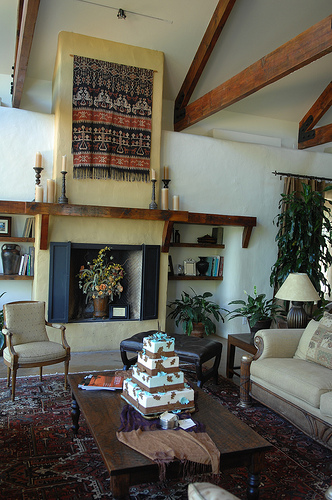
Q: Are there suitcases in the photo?
A: No, there are no suitcases.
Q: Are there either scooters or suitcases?
A: No, there are no suitcases or scooters.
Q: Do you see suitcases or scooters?
A: No, there are no suitcases or scooters.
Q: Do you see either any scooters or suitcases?
A: No, there are no suitcases or scooters.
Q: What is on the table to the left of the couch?
A: The plant is on the table.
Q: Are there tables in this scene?
A: Yes, there is a table.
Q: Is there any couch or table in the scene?
A: Yes, there is a table.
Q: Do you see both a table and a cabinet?
A: No, there is a table but no cabinets.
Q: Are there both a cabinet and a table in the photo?
A: No, there is a table but no cabinets.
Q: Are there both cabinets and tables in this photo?
A: No, there is a table but no cabinets.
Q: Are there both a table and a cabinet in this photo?
A: No, there is a table but no cabinets.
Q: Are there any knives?
A: No, there are no knives.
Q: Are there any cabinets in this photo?
A: No, there are no cabinets.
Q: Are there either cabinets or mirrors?
A: No, there are no cabinets or mirrors.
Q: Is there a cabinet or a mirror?
A: No, there are no cabinets or mirrors.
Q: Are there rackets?
A: No, there are no rackets.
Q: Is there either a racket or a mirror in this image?
A: No, there are no rackets or mirrors.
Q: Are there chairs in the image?
A: Yes, there is a chair.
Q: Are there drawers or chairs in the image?
A: Yes, there is a chair.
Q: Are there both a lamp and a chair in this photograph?
A: Yes, there are both a chair and a lamp.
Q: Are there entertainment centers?
A: No, there are no entertainment centers.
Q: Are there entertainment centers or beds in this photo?
A: No, there are no entertainment centers or beds.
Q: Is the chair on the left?
A: Yes, the chair is on the left of the image.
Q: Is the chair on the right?
A: No, the chair is on the left of the image.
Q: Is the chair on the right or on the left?
A: The chair is on the left of the image.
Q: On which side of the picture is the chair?
A: The chair is on the left of the image.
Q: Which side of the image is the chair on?
A: The chair is on the left of the image.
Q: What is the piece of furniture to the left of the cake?
A: The piece of furniture is a chair.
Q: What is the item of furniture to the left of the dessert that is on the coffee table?
A: The piece of furniture is a chair.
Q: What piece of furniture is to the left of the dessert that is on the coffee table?
A: The piece of furniture is a chair.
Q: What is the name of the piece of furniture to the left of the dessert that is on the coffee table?
A: The piece of furniture is a chair.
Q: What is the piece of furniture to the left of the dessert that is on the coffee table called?
A: The piece of furniture is a chair.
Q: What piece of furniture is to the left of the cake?
A: The piece of furniture is a chair.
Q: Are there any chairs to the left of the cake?
A: Yes, there is a chair to the left of the cake.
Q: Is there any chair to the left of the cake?
A: Yes, there is a chair to the left of the cake.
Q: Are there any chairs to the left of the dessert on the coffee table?
A: Yes, there is a chair to the left of the cake.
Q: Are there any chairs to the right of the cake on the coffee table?
A: No, the chair is to the left of the cake.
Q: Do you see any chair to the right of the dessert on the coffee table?
A: No, the chair is to the left of the cake.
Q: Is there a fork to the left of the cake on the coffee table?
A: No, there is a chair to the left of the cake.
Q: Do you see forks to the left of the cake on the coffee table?
A: No, there is a chair to the left of the cake.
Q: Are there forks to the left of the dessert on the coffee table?
A: No, there is a chair to the left of the cake.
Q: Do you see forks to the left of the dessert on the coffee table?
A: No, there is a chair to the left of the cake.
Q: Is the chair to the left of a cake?
A: Yes, the chair is to the left of a cake.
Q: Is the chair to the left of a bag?
A: No, the chair is to the left of a cake.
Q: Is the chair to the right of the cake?
A: No, the chair is to the left of the cake.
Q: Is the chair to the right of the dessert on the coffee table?
A: No, the chair is to the left of the cake.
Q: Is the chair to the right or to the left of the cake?
A: The chair is to the left of the cake.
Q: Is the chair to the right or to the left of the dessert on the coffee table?
A: The chair is to the left of the cake.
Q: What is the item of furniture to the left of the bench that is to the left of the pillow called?
A: The piece of furniture is a chair.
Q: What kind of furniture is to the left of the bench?
A: The piece of furniture is a chair.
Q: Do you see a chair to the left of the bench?
A: Yes, there is a chair to the left of the bench.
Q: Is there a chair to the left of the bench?
A: Yes, there is a chair to the left of the bench.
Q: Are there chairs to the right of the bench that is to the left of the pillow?
A: No, the chair is to the left of the bench.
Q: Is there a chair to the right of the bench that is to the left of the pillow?
A: No, the chair is to the left of the bench.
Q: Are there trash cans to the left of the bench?
A: No, there is a chair to the left of the bench.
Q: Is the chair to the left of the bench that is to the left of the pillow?
A: Yes, the chair is to the left of the bench.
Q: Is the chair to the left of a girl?
A: No, the chair is to the left of the bench.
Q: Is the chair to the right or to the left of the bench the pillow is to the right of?
A: The chair is to the left of the bench.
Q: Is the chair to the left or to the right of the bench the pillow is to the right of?
A: The chair is to the left of the bench.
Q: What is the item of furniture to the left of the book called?
A: The piece of furniture is a chair.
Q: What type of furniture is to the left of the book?
A: The piece of furniture is a chair.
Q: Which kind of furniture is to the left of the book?
A: The piece of furniture is a chair.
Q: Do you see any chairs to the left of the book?
A: Yes, there is a chair to the left of the book.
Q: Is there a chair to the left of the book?
A: Yes, there is a chair to the left of the book.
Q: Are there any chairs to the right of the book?
A: No, the chair is to the left of the book.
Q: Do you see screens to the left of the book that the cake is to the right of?
A: No, there is a chair to the left of the book.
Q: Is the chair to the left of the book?
A: Yes, the chair is to the left of the book.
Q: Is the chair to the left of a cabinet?
A: No, the chair is to the left of the book.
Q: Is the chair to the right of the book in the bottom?
A: No, the chair is to the left of the book.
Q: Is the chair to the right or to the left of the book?
A: The chair is to the left of the book.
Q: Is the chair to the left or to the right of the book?
A: The chair is to the left of the book.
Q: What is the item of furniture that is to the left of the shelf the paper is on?
A: The piece of furniture is a chair.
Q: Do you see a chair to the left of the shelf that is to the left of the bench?
A: Yes, there is a chair to the left of the shelf.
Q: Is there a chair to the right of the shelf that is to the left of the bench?
A: No, the chair is to the left of the shelf.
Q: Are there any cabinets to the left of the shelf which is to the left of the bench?
A: No, there is a chair to the left of the shelf.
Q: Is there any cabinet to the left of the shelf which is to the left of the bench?
A: No, there is a chair to the left of the shelf.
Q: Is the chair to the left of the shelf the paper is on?
A: Yes, the chair is to the left of the shelf.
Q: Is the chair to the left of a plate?
A: No, the chair is to the left of the shelf.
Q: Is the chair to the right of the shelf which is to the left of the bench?
A: No, the chair is to the left of the shelf.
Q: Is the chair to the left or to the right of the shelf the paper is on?
A: The chair is to the left of the shelf.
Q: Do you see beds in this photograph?
A: No, there are no beds.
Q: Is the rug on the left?
A: Yes, the rug is on the left of the image.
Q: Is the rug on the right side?
A: No, the rug is on the left of the image.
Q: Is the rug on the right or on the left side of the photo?
A: The rug is on the left of the image.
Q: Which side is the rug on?
A: The rug is on the left of the image.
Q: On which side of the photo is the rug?
A: The rug is on the left of the image.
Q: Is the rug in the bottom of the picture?
A: Yes, the rug is in the bottom of the image.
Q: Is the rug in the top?
A: No, the rug is in the bottom of the image.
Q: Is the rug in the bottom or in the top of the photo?
A: The rug is in the bottom of the image.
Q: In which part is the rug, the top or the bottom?
A: The rug is in the bottom of the image.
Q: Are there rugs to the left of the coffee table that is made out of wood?
A: Yes, there is a rug to the left of the coffee table.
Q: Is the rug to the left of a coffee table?
A: Yes, the rug is to the left of a coffee table.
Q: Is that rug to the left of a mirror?
A: No, the rug is to the left of a coffee table.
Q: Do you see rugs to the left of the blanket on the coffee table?
A: Yes, there is a rug to the left of the blanket.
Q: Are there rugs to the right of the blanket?
A: No, the rug is to the left of the blanket.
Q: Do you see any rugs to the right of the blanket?
A: No, the rug is to the left of the blanket.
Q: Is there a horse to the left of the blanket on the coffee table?
A: No, there is a rug to the left of the blanket.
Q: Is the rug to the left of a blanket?
A: Yes, the rug is to the left of a blanket.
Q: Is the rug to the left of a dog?
A: No, the rug is to the left of a blanket.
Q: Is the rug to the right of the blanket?
A: No, the rug is to the left of the blanket.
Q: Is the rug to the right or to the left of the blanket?
A: The rug is to the left of the blanket.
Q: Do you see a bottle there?
A: No, there are no bottles.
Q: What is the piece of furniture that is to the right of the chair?
A: The piece of furniture is a shelf.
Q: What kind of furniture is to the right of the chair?
A: The piece of furniture is a shelf.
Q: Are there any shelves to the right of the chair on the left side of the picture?
A: Yes, there is a shelf to the right of the chair.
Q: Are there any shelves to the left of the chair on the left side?
A: No, the shelf is to the right of the chair.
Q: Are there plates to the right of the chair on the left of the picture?
A: No, there is a shelf to the right of the chair.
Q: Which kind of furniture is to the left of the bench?
A: The piece of furniture is a shelf.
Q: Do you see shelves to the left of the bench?
A: Yes, there is a shelf to the left of the bench.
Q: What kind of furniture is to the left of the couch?
A: The piece of furniture is a shelf.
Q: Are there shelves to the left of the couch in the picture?
A: Yes, there is a shelf to the left of the couch.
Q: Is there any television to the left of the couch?
A: No, there is a shelf to the left of the couch.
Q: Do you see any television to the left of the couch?
A: No, there is a shelf to the left of the couch.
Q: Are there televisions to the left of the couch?
A: No, there is a shelf to the left of the couch.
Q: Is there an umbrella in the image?
A: No, there are no umbrellas.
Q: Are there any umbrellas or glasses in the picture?
A: No, there are no umbrellas or glasses.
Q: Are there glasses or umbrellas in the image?
A: No, there are no umbrellas or glasses.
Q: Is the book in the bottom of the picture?
A: Yes, the book is in the bottom of the image.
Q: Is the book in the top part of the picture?
A: No, the book is in the bottom of the image.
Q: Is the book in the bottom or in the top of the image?
A: The book is in the bottom of the image.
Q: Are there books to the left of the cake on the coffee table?
A: Yes, there is a book to the left of the cake.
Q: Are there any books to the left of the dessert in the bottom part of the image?
A: Yes, there is a book to the left of the cake.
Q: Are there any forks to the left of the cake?
A: No, there is a book to the left of the cake.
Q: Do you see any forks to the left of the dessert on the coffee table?
A: No, there is a book to the left of the cake.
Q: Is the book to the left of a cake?
A: Yes, the book is to the left of a cake.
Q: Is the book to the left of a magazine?
A: No, the book is to the left of a cake.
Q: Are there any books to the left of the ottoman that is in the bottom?
A: Yes, there is a book to the left of the ottoman.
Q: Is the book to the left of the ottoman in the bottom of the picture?
A: Yes, the book is to the left of the ottoman.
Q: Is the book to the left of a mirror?
A: No, the book is to the left of the ottoman.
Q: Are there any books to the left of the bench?
A: Yes, there is a book to the left of the bench.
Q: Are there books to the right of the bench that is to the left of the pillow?
A: No, the book is to the left of the bench.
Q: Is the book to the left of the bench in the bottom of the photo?
A: Yes, the book is to the left of the bench.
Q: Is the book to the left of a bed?
A: No, the book is to the left of the bench.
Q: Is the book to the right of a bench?
A: No, the book is to the left of a bench.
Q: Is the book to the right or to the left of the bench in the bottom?
A: The book is to the left of the bench.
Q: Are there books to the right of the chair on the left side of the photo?
A: Yes, there is a book to the right of the chair.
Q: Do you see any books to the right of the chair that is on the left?
A: Yes, there is a book to the right of the chair.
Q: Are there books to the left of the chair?
A: No, the book is to the right of the chair.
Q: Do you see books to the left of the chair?
A: No, the book is to the right of the chair.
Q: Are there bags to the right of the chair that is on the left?
A: No, there is a book to the right of the chair.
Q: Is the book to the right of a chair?
A: Yes, the book is to the right of a chair.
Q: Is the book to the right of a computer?
A: No, the book is to the right of a chair.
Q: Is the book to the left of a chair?
A: No, the book is to the right of a chair.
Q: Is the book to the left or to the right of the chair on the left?
A: The book is to the right of the chair.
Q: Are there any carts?
A: No, there are no carts.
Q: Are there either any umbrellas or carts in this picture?
A: No, there are no carts or umbrellas.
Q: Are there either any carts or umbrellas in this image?
A: No, there are no carts or umbrellas.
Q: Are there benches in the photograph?
A: Yes, there is a bench.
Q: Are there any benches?
A: Yes, there is a bench.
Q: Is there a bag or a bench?
A: Yes, there is a bench.